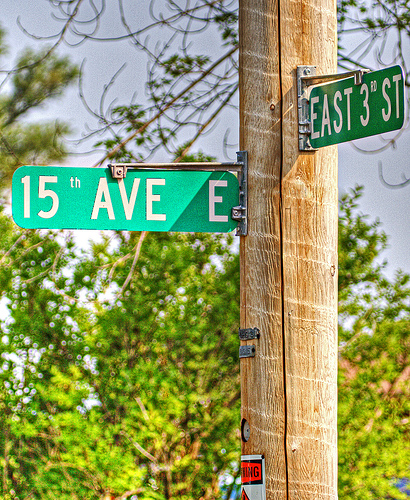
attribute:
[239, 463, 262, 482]
text — black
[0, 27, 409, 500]
trees — green, blurry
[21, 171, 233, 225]
text — white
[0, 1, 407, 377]
sky — gray, clear, blue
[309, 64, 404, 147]
board — green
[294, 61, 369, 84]
hanger — small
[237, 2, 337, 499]
post — brown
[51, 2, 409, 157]
branches — blurry, bare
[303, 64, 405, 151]
street sign — green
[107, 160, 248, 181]
bracket — metal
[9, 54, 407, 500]
leaves — green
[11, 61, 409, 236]
signs — hanging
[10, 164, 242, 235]
sign — green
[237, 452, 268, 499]
sign — partially visible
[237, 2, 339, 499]
pole — wooden, large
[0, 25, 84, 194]
tree — green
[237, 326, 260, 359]
clasps — metal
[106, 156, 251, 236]
holder — metal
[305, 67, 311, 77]
screw — small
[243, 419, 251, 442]
screw — large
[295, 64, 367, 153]
attachment — metallic